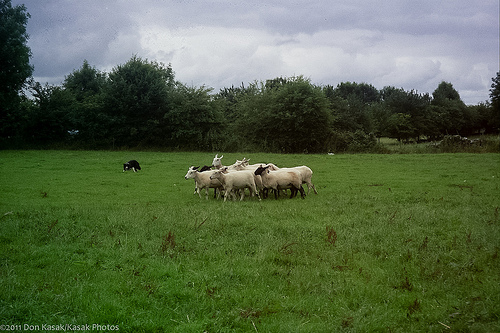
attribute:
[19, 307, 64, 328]
name — photographer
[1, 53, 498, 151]
trees — distant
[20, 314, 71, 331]
name — photographer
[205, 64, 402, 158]
trees — green, small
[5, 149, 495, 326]
grass — green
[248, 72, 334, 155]
tree — branched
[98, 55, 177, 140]
tree — branched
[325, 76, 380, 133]
tree — branched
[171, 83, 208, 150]
tree — branched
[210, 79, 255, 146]
tree — branched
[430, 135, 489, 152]
cut wood — stacked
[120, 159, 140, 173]
collie — Border collie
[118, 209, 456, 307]
field — large, grassy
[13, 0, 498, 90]
clouds — white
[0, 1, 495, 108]
sky — with clouds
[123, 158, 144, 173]
animal — black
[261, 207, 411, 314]
grass — green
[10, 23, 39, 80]
leaves — green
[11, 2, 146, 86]
cloud — rain cloud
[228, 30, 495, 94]
cloud — rain cloud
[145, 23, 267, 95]
cloud — rain cloud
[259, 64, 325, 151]
tree — big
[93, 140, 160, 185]
animal — black, white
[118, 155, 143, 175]
animal — black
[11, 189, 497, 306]
grass — long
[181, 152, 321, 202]
flock — sheep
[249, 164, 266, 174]
face — black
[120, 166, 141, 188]
feet — white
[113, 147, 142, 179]
animal — black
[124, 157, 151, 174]
dog — black, white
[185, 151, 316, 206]
goats — grouped, white, many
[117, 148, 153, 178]
animal — black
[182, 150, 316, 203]
sheep — herd, walking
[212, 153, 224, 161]
ears — pointy